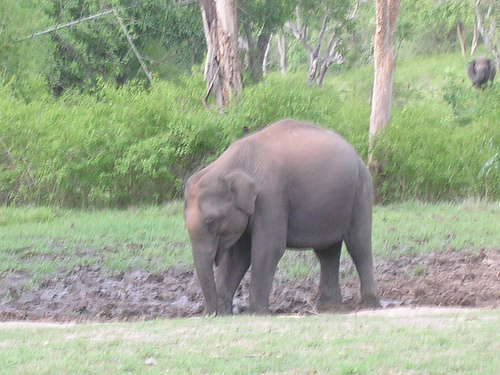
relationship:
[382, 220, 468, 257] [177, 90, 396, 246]
ground by elephant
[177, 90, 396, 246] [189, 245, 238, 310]
elephant has trunk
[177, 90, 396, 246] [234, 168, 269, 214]
elephant has ear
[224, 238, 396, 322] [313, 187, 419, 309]
legs on back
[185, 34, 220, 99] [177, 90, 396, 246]
tree behind elephant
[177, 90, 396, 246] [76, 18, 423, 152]
elephant in background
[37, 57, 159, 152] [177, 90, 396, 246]
bushes behind elephant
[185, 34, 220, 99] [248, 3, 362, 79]
tree with branches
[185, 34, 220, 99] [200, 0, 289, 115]
tree has trunk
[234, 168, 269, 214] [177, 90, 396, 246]
ear of elephant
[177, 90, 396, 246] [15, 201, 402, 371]
elephant in field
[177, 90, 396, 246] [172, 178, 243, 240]
elephant has head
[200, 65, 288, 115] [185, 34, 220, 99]
trunk of tree